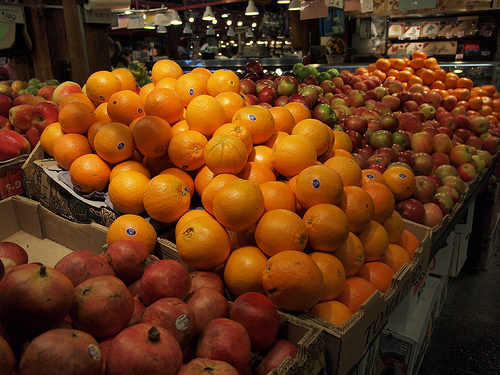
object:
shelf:
[351, 271, 441, 374]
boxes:
[374, 272, 441, 374]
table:
[373, 275, 442, 345]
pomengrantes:
[196, 317, 250, 368]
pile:
[38, 58, 430, 334]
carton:
[0, 194, 329, 375]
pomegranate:
[140, 296, 200, 355]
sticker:
[173, 312, 193, 332]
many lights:
[109, 0, 262, 41]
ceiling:
[133, 2, 295, 5]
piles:
[226, 76, 499, 228]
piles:
[341, 49, 499, 136]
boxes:
[421, 201, 477, 279]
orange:
[292, 164, 345, 209]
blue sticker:
[311, 179, 320, 189]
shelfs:
[383, 9, 499, 66]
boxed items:
[420, 23, 442, 41]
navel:
[93, 120, 135, 164]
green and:
[368, 129, 396, 149]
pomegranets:
[103, 322, 182, 374]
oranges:
[201, 132, 248, 177]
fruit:
[210, 177, 265, 233]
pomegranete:
[69, 274, 135, 342]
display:
[0, 240, 326, 374]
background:
[0, 0, 499, 374]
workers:
[146, 22, 202, 61]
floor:
[417, 256, 499, 374]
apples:
[409, 130, 435, 158]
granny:
[289, 62, 341, 83]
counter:
[145, 56, 306, 70]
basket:
[198, 42, 220, 58]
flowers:
[331, 44, 338, 51]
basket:
[324, 55, 348, 67]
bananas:
[126, 60, 148, 84]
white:
[202, 13, 215, 22]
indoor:
[0, 0, 499, 374]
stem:
[36, 263, 45, 278]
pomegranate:
[0, 261, 79, 335]